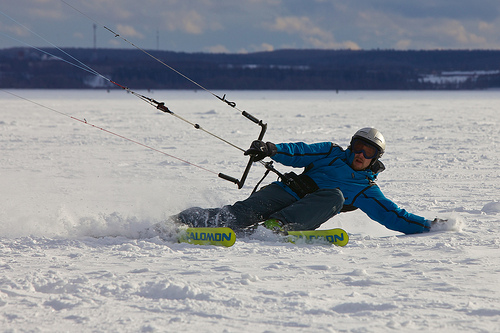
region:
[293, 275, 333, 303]
part of the snow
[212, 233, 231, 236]
edge of a board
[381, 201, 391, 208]
part of a jacket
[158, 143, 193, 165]
part of a rope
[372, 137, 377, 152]
part of an helmet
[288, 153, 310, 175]
part of a jacket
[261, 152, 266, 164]
part of a glove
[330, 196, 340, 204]
part of a knee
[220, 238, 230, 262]
edge of a board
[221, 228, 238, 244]
side of a board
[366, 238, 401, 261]
part of the snow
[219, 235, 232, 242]
edge of a board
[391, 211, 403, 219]
part of a jacket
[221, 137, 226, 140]
part of a rope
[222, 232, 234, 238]
edge of a board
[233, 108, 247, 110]
edge of a rope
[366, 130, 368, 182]
part of an helmet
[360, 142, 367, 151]
part of a shadow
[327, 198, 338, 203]
part of a knee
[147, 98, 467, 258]
snow skier being towed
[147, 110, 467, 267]
man on skis being towed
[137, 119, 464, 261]
guy on skis being towed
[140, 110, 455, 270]
person on skis being towed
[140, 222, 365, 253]
yellow bottoms of skis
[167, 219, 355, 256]
bottoms of skis with writing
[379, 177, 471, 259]
left hand touching the snow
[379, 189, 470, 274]
left hand touching the surface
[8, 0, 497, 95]
wooded mountains in background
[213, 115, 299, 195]
ropes attached to man's belt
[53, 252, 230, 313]
snow is white in color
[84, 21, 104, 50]
pole is blurry in background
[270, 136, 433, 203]
man is wearing a blue coat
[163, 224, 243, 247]
blue and yellow ski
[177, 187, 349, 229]
man is wearing gray pants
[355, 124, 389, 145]
man is wearing silver helmet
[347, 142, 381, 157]
man is wearing goggles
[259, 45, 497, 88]
small hills in background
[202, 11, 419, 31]
sky is blue with some clouds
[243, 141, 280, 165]
man is wearing black glove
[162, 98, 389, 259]
person para skiing in white snow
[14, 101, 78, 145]
whaie snow on hill side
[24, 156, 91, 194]
whaie snow on hill side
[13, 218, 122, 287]
whaie snow on hill side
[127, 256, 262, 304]
whaie snow on hill side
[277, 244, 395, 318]
whaie snow on hill side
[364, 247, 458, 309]
whaie snow on hill side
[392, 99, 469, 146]
whaie snow on hill side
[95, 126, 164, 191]
whaie snow on hill side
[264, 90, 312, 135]
whaie snow on hill side